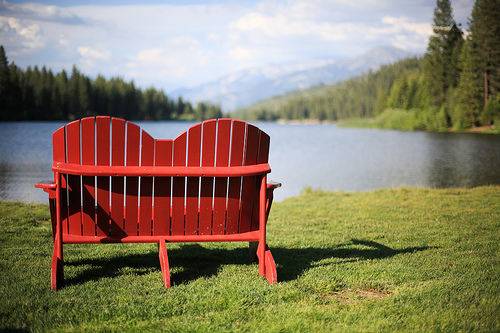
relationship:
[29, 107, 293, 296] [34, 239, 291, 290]
bench has legs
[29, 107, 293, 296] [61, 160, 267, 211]
bench has back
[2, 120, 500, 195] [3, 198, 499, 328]
water near grass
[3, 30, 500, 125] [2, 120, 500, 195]
trees around water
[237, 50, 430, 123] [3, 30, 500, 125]
mountains behind trees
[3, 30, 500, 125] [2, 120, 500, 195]
trees behind water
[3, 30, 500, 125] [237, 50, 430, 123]
trees near mountains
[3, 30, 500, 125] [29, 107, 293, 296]
trees in front of bench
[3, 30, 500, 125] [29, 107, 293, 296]
trees near bench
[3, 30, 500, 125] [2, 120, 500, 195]
trees next to water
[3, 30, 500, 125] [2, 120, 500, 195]
trees beyond water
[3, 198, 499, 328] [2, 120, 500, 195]
grass next to water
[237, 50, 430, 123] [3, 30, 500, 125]
mountains beyond trees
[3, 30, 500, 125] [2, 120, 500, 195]
trees along water